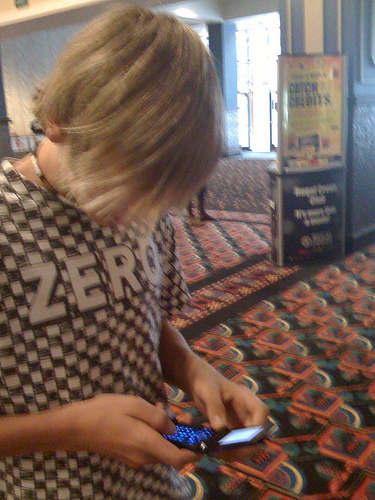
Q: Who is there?
A: Boy.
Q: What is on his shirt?
A: ZERO.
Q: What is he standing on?
A: Carpet.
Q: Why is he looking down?
A: Cellphone.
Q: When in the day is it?
A: Afternoon.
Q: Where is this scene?
A: Movie theatre.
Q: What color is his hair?
A: Blonde.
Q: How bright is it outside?
A: Very bright.